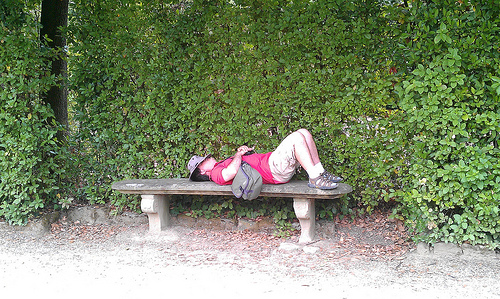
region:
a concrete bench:
[107, 166, 359, 221]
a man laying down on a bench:
[133, 127, 365, 204]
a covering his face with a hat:
[173, 134, 221, 191]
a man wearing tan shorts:
[181, 121, 338, 213]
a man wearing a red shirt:
[194, 127, 274, 191]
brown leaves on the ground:
[113, 215, 418, 267]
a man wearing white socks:
[290, 140, 335, 193]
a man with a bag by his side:
[183, 125, 286, 210]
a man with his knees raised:
[172, 104, 362, 188]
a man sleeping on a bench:
[94, 108, 374, 240]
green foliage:
[121, 45, 189, 100]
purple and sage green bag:
[230, 155, 263, 202]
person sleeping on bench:
[108, 117, 361, 248]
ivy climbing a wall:
[25, 5, 107, 226]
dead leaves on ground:
[183, 215, 268, 260]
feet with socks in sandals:
[297, 153, 354, 203]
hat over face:
[172, 136, 223, 191]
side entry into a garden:
[21, 5, 86, 231]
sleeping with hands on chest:
[183, 135, 364, 202]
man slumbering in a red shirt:
[177, 116, 355, 206]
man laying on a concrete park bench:
[140, 105, 356, 269]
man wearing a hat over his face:
[173, 126, 352, 203]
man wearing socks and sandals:
[181, 111, 348, 207]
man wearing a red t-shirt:
[172, 120, 346, 213]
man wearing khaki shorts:
[164, 92, 381, 207]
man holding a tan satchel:
[175, 118, 366, 206]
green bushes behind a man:
[151, 15, 372, 224]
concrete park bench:
[104, 169, 198, 244]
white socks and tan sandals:
[301, 155, 350, 200]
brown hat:
[181, 141, 213, 180]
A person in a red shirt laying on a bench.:
[186, 127, 343, 188]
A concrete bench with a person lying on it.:
[107, 172, 354, 242]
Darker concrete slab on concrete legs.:
[108, 174, 353, 201]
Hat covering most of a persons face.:
[180, 150, 217, 182]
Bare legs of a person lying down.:
[286, 126, 321, 170]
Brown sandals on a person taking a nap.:
[305, 172, 347, 191]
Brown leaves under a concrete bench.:
[186, 223, 286, 245]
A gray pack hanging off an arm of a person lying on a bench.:
[228, 164, 263, 202]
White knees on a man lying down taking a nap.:
[287, 123, 312, 150]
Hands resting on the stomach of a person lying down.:
[231, 142, 256, 155]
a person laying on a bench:
[89, 102, 461, 295]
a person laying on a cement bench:
[87, 91, 361, 231]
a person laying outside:
[93, 38, 473, 260]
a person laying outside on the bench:
[47, 23, 396, 224]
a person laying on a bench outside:
[107, 71, 359, 241]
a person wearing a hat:
[170, 135, 398, 230]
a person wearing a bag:
[164, 104, 339, 226]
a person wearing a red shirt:
[175, 105, 360, 194]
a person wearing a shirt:
[177, 99, 343, 206]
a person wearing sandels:
[180, 120, 360, 215]